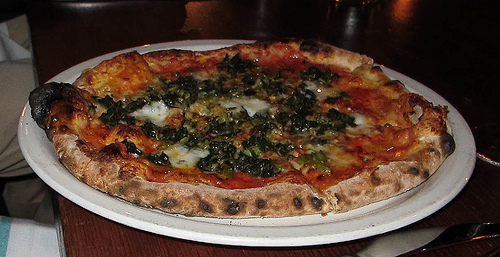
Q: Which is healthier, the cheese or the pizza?
A: The cheese is healthier than the pizza.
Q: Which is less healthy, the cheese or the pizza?
A: The pizza is less healthy than the cheese.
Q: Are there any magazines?
A: No, there are no magazines.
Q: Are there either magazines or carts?
A: No, there are no magazines or carts.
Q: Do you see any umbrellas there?
A: No, there are no umbrellas.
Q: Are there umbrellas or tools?
A: No, there are no umbrellas or tools.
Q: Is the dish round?
A: Yes, the dish is round.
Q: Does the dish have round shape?
A: Yes, the dish is round.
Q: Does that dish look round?
A: Yes, the dish is round.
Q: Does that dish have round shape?
A: Yes, the dish is round.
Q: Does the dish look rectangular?
A: No, the dish is round.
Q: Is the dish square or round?
A: The dish is round.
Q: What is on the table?
A: The dish is on the table.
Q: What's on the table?
A: The dish is on the table.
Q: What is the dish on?
A: The dish is on the table.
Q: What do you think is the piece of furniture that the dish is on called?
A: The piece of furniture is a table.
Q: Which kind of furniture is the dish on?
A: The dish is on the table.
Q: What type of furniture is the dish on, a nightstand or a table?
A: The dish is on a table.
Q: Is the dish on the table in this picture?
A: Yes, the dish is on the table.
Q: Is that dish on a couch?
A: No, the dish is on the table.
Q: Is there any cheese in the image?
A: Yes, there is cheese.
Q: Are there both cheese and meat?
A: No, there is cheese but no meat.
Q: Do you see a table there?
A: Yes, there is a table.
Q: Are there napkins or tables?
A: Yes, there is a table.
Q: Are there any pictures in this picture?
A: No, there are no pictures.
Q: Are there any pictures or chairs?
A: No, there are no pictures or chairs.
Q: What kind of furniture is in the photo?
A: The furniture is a table.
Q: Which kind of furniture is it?
A: The piece of furniture is a table.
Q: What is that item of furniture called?
A: This is a table.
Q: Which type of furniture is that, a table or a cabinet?
A: This is a table.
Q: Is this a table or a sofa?
A: This is a table.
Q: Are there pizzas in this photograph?
A: Yes, there is a pizza.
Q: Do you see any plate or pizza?
A: Yes, there is a pizza.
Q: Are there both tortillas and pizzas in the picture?
A: No, there is a pizza but no tortillas.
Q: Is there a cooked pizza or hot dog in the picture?
A: Yes, there is a cooked pizza.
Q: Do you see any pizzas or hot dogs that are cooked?
A: Yes, the pizza is cooked.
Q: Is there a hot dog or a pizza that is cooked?
A: Yes, the pizza is cooked.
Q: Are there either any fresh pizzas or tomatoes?
A: Yes, there is a fresh pizza.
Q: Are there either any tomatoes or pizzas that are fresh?
A: Yes, the pizza is fresh.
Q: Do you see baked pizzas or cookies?
A: Yes, there is a baked pizza.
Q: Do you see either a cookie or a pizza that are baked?
A: Yes, the pizza is baked.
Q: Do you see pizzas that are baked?
A: Yes, there is a baked pizza.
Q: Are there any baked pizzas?
A: Yes, there is a baked pizza.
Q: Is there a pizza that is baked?
A: Yes, there is a pizza that is baked.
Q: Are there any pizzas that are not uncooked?
A: Yes, there is an baked pizza.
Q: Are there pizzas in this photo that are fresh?
A: Yes, there is a fresh pizza.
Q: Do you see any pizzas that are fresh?
A: Yes, there is a pizza that is fresh.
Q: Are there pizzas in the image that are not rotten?
A: Yes, there is a fresh pizza.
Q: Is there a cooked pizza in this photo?
A: Yes, there is a cooked pizza.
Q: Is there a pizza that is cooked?
A: Yes, there is a pizza that is cooked.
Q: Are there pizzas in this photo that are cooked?
A: Yes, there is a pizza that is cooked.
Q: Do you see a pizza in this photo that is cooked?
A: Yes, there is a pizza that is cooked.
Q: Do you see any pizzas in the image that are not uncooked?
A: Yes, there is an cooked pizza.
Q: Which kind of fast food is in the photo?
A: The fast food is a pizza.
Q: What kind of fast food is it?
A: The food is a pizza.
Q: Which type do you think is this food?
A: This is a pizza.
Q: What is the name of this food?
A: This is a pizza.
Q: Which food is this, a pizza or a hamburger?
A: This is a pizza.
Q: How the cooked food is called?
A: The food is a pizza.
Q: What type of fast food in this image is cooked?
A: The fast food is a pizza.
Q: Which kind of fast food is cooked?
A: The fast food is a pizza.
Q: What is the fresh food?
A: The food is a pizza.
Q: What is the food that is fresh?
A: The food is a pizza.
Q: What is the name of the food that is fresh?
A: The food is a pizza.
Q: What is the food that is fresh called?
A: The food is a pizza.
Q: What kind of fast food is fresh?
A: The fast food is a pizza.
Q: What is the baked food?
A: The food is a pizza.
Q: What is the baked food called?
A: The food is a pizza.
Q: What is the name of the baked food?
A: The food is a pizza.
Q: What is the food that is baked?
A: The food is a pizza.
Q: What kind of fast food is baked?
A: The fast food is a pizza.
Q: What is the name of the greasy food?
A: The food is a pizza.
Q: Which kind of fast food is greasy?
A: The fast food is a pizza.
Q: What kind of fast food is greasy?
A: The fast food is a pizza.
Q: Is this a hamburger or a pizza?
A: This is a pizza.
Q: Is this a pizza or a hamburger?
A: This is a pizza.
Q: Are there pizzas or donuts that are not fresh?
A: No, there is a pizza but it is fresh.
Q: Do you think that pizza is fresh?
A: Yes, the pizza is fresh.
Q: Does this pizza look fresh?
A: Yes, the pizza is fresh.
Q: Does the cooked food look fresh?
A: Yes, the pizza is fresh.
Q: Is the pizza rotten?
A: No, the pizza is fresh.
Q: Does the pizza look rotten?
A: No, the pizza is fresh.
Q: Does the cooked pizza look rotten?
A: No, the pizza is fresh.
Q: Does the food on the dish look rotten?
A: No, the pizza is fresh.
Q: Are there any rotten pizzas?
A: No, there is a pizza but it is fresh.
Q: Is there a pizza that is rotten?
A: No, there is a pizza but it is fresh.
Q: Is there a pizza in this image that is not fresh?
A: No, there is a pizza but it is fresh.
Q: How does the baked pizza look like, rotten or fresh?
A: The pizza is fresh.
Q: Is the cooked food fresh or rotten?
A: The pizza is fresh.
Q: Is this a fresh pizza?
A: Yes, this is a fresh pizza.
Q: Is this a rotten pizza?
A: No, this is a fresh pizza.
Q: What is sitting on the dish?
A: The pizza is sitting on the dish.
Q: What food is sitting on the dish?
A: The food is a pizza.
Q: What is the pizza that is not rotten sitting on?
A: The pizza is sitting on the dish.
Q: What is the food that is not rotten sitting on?
A: The pizza is sitting on the dish.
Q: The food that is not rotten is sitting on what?
A: The pizza is sitting on the dish.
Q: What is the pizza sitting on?
A: The pizza is sitting on the dish.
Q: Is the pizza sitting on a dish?
A: Yes, the pizza is sitting on a dish.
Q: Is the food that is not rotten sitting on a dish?
A: Yes, the pizza is sitting on a dish.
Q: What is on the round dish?
A: The pizza is on the dish.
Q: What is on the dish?
A: The pizza is on the dish.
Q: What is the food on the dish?
A: The food is a pizza.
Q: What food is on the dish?
A: The food is a pizza.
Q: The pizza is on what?
A: The pizza is on the dish.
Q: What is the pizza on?
A: The pizza is on the dish.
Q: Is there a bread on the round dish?
A: No, there is a pizza on the dish.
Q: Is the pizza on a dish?
A: Yes, the pizza is on a dish.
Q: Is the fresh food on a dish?
A: Yes, the pizza is on a dish.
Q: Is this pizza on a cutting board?
A: No, the pizza is on a dish.